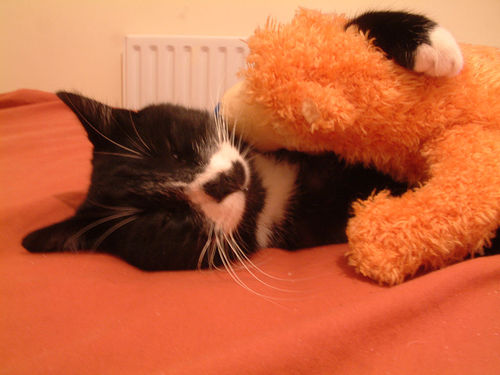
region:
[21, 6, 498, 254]
A black and white kitten asleep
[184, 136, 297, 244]
White markings on a black cat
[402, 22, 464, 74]
A cat's white paw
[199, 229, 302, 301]
White whiskers on the bed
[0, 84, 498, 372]
A light red bed sheet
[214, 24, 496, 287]
An orange stuffed animal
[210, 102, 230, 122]
The stuffed animal's blue nose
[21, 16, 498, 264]
A cat hugging a stuffed animal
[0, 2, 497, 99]
The white wall of the room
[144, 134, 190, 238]
The cat's closed eyes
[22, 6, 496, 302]
Black and white cat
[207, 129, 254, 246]
Black spot on cats nose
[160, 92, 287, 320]
White whiskers on cat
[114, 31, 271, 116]
White a/c on wall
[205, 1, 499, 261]
Orange teddy bear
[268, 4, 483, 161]
Black and white cat paw holding onto teddy bear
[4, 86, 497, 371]
Cat is laying on pink blanket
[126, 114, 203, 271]
Cats eyes are closed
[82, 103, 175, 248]
Cat has white whiskers on eyebrows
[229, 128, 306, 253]
White chest on cat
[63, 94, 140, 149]
Cat has black ear.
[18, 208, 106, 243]
Cat has black ear.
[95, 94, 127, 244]
Cat has white eyelashes.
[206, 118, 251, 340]
Cat has white whiskers.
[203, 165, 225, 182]
Cat has black nose.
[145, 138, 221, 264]
Cat's eyes are shut.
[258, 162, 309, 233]
Cat has white markings on neck.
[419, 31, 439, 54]
Tip of cat's paw is white.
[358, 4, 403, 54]
Cat has black leg.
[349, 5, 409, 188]
Cat is holding orange stuffed animal.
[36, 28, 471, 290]
cat hugging a toy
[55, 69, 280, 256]
a black and white cat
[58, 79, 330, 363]
a black and white cat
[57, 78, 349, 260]
black and white cat on bed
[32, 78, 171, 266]
cat has black ears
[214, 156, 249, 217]
cat has black nose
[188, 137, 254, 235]
cat has white patch on face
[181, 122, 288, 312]
cat has white whiskers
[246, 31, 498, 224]
brown stuffed toy on cat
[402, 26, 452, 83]
cat has white paw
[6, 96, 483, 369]
blanket on bed is sand colored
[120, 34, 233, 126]
white vent on wall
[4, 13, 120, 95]
tan wall behind bed